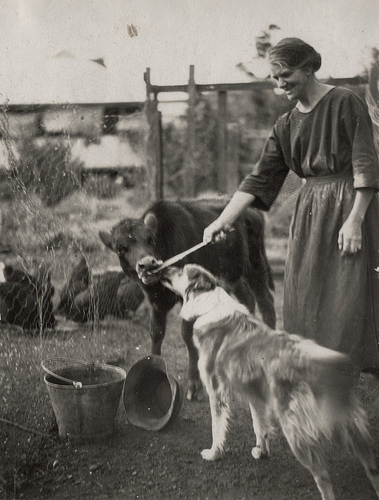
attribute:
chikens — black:
[71, 268, 129, 319]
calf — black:
[100, 187, 283, 346]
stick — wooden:
[136, 230, 233, 274]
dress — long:
[236, 83, 378, 373]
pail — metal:
[38, 351, 129, 444]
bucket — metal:
[40, 354, 125, 441]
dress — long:
[280, 178, 377, 358]